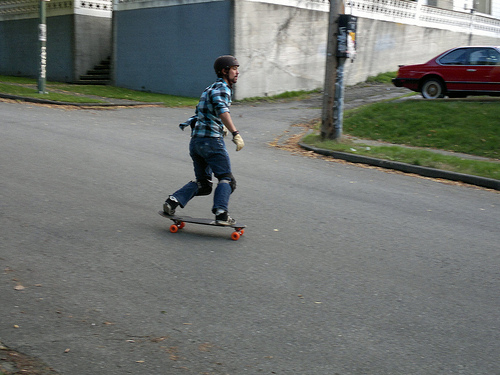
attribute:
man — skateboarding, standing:
[161, 55, 246, 224]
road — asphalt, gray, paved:
[1, 98, 500, 374]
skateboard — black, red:
[156, 205, 247, 239]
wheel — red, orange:
[227, 229, 241, 242]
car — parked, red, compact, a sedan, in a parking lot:
[390, 38, 500, 102]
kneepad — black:
[212, 170, 241, 193]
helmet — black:
[213, 53, 240, 82]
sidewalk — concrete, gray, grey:
[344, 134, 496, 178]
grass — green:
[1, 71, 204, 118]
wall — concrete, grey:
[110, 1, 236, 101]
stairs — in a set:
[76, 50, 117, 90]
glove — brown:
[230, 132, 247, 153]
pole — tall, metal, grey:
[37, 1, 50, 94]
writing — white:
[39, 45, 48, 82]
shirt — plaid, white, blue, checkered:
[177, 74, 233, 139]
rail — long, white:
[250, 1, 500, 42]